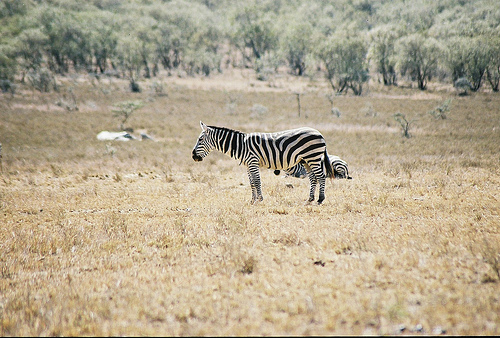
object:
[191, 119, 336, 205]
zebra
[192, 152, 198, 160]
snout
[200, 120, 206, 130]
ear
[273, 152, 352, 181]
zebra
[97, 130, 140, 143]
rock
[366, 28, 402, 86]
tree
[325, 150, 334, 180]
tail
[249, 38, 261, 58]
branch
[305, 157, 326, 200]
leg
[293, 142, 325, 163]
stripe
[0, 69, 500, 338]
field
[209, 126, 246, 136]
mane